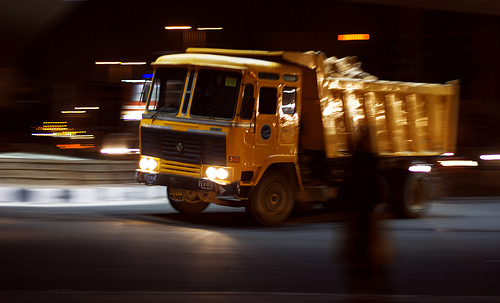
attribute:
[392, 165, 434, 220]
rear tire — black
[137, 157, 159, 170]
lights — lit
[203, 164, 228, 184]
lights — lit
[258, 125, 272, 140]
decal — blue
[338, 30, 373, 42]
orange light — lit up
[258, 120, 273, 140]
decal — blue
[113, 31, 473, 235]
truck — large, dump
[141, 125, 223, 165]
grill — black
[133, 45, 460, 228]
yellow truck — dump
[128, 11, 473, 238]
truck — yellow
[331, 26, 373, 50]
light — orange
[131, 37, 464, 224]
truck — yellow, construction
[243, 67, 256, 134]
arm — yellow